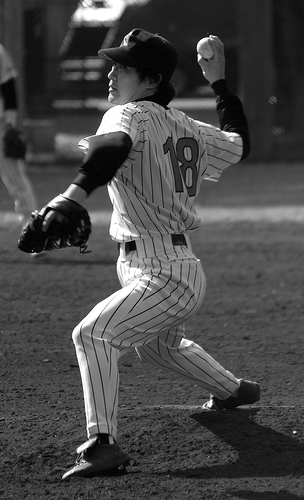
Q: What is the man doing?
A: Pitching.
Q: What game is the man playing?
A: Baseball.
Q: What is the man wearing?
A: A uniform.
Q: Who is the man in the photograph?
A: A famous pitcher.